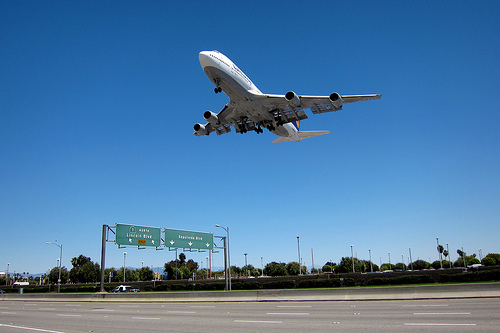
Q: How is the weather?
A: It is clear.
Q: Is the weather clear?
A: Yes, it is clear.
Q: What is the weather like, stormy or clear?
A: It is clear.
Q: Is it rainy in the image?
A: No, it is clear.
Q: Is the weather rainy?
A: No, it is clear.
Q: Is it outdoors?
A: Yes, it is outdoors.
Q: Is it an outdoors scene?
A: Yes, it is outdoors.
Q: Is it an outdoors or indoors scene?
A: It is outdoors.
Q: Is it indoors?
A: No, it is outdoors.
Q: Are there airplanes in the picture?
A: Yes, there is an airplane.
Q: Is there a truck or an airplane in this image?
A: Yes, there is an airplane.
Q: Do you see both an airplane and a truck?
A: No, there is an airplane but no trucks.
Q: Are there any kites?
A: No, there are no kites.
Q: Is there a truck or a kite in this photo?
A: No, there are no kites or trucks.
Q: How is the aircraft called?
A: The aircraft is an airplane.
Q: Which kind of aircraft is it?
A: The aircraft is an airplane.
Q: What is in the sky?
A: The airplane is in the sky.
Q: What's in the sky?
A: The airplane is in the sky.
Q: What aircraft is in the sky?
A: The aircraft is an airplane.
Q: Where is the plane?
A: The plane is in the sky.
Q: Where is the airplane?
A: The plane is in the sky.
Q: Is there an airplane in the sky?
A: Yes, there is an airplane in the sky.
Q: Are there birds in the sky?
A: No, there is an airplane in the sky.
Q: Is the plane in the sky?
A: Yes, the plane is in the sky.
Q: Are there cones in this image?
A: No, there are no cones.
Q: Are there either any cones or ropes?
A: No, there are no cones or ropes.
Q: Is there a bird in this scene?
A: No, there are no birds.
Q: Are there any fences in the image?
A: No, there are no fences.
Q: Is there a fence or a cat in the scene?
A: No, there are no fences or cats.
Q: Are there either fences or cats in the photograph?
A: No, there are no fences or cats.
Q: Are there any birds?
A: No, there are no birds.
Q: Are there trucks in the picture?
A: No, there are no trucks.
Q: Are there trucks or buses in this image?
A: No, there are no trucks or buses.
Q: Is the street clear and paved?
A: Yes, the street is clear and paved.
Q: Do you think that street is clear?
A: Yes, the street is clear.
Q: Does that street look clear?
A: Yes, the street is clear.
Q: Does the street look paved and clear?
A: Yes, the street is paved and clear.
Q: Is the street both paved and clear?
A: Yes, the street is paved and clear.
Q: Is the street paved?
A: Yes, the street is paved.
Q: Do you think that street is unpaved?
A: No, the street is paved.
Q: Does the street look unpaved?
A: No, the street is paved.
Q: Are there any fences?
A: No, there are no fences.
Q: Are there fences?
A: No, there are no fences.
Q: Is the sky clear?
A: Yes, the sky is clear.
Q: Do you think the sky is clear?
A: Yes, the sky is clear.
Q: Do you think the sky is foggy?
A: No, the sky is clear.